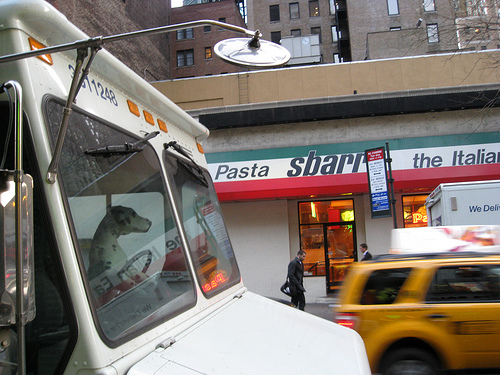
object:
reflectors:
[119, 96, 146, 121]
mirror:
[215, 29, 288, 69]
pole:
[1, 17, 224, 63]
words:
[215, 147, 498, 179]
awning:
[201, 56, 498, 124]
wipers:
[66, 130, 162, 205]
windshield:
[170, 128, 243, 343]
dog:
[89, 205, 154, 308]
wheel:
[360, 328, 450, 374]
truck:
[6, 5, 370, 374]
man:
[277, 250, 312, 320]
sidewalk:
[305, 294, 365, 326]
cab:
[332, 253, 499, 366]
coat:
[285, 262, 309, 290]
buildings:
[173, 4, 483, 78]